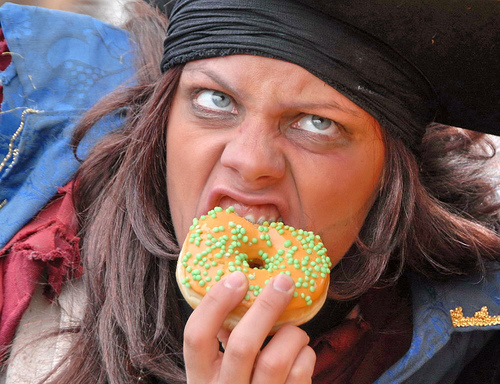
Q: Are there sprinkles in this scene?
A: Yes, there are sprinkles.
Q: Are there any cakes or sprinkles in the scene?
A: Yes, there are sprinkles.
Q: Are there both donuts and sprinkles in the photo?
A: Yes, there are both sprinkles and a donut.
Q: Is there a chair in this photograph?
A: No, there are no chairs.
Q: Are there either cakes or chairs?
A: No, there are no chairs or cakes.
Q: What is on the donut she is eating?
A: The sprinkles are on the donut.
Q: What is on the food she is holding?
A: The sprinkles are on the donut.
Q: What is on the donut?
A: The sprinkles are on the donut.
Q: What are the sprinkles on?
A: The sprinkles are on the donut.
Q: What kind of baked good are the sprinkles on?
A: The sprinkles are on the donut.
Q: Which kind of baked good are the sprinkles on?
A: The sprinkles are on the donut.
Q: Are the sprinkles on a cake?
A: No, the sprinkles are on the donut.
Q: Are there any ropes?
A: No, there are no ropes.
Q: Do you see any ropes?
A: No, there are no ropes.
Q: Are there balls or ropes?
A: No, there are no ropes or balls.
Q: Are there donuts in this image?
A: Yes, there is a donut.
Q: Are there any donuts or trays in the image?
A: Yes, there is a donut.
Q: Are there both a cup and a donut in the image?
A: No, there is a donut but no cups.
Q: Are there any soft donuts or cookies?
A: Yes, there is a soft donut.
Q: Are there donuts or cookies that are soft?
A: Yes, the donut is soft.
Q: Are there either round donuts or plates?
A: Yes, there is a round donut.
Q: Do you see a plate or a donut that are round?
A: Yes, the donut is round.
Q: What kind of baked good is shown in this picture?
A: The baked good is a donut.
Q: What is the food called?
A: The food is a donut.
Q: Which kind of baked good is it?
A: The food is a donut.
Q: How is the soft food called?
A: The food is a donut.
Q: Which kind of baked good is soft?
A: The baked good is a donut.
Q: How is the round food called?
A: The food is a donut.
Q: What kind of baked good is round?
A: The baked good is a donut.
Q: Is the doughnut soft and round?
A: Yes, the doughnut is soft and round.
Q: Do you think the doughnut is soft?
A: Yes, the doughnut is soft.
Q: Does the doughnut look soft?
A: Yes, the doughnut is soft.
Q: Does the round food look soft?
A: Yes, the doughnut is soft.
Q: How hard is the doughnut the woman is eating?
A: The doughnut is soft.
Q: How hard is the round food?
A: The doughnut is soft.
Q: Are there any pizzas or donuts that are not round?
A: No, there is a donut but it is round.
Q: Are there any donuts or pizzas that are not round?
A: No, there is a donut but it is round.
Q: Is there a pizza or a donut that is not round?
A: No, there is a donut but it is round.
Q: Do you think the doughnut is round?
A: Yes, the doughnut is round.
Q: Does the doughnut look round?
A: Yes, the doughnut is round.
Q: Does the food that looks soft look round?
A: Yes, the doughnut is round.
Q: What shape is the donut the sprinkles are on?
A: The donut is round.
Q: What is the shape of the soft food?
A: The donut is round.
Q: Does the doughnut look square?
A: No, the doughnut is round.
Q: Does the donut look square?
A: No, the donut is round.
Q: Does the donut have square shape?
A: No, the donut is round.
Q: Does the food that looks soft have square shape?
A: No, the donut is round.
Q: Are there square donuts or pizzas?
A: No, there is a donut but it is round.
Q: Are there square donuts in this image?
A: No, there is a donut but it is round.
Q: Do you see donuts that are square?
A: No, there is a donut but it is round.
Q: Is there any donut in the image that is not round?
A: No, there is a donut but it is round.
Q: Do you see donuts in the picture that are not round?
A: No, there is a donut but it is round.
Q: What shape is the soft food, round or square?
A: The donut is round.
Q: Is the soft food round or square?
A: The donut is round.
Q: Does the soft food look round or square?
A: The donut is round.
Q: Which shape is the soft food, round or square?
A: The donut is round.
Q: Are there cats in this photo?
A: No, there are no cats.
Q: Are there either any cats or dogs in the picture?
A: No, there are no cats or dogs.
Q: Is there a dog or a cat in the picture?
A: No, there are no cats or dogs.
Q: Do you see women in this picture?
A: Yes, there is a woman.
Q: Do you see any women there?
A: Yes, there is a woman.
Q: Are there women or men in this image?
A: Yes, there is a woman.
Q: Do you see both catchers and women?
A: No, there is a woman but no catchers.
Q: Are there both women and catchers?
A: No, there is a woman but no catchers.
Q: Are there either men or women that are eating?
A: Yes, the woman is eating.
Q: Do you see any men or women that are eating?
A: Yes, the woman is eating.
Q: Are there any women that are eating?
A: Yes, there is a woman that is eating.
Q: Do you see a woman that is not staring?
A: Yes, there is a woman that is eating .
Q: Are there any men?
A: No, there are no men.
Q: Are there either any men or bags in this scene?
A: No, there are no men or bags.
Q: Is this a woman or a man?
A: This is a woman.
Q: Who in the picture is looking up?
A: The woman is looking up.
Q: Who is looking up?
A: The woman is looking up.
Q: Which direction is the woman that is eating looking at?
A: The woman is looking up.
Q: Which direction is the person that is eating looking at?
A: The woman is looking up.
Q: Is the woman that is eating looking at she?
A: Yes, the woman is looking up.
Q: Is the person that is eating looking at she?
A: Yes, the woman is looking up.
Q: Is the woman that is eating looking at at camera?
A: No, the woman is looking up.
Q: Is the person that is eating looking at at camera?
A: No, the woman is looking up.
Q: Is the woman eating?
A: Yes, the woman is eating.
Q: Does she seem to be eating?
A: Yes, the woman is eating.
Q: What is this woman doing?
A: The woman is eating.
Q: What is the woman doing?
A: The woman is eating.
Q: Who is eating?
A: The woman is eating.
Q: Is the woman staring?
A: No, the woman is eating.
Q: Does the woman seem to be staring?
A: No, the woman is eating.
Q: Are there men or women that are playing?
A: No, there is a woman but she is eating.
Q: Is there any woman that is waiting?
A: No, there is a woman but she is eating.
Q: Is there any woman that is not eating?
A: No, there is a woman but she is eating.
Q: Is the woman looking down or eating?
A: The woman is eating.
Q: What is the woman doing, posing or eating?
A: The woman is eating.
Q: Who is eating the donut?
A: The woman is eating the donut.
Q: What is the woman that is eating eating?
A: The woman is eating a donut.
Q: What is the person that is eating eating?
A: The woman is eating a donut.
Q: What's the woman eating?
A: The woman is eating a donut.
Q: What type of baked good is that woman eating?
A: The woman is eating a doughnut.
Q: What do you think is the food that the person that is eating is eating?
A: The food is a donut.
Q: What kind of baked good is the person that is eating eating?
A: The woman is eating a doughnut.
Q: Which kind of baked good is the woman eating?
A: The woman is eating a doughnut.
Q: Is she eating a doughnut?
A: Yes, the woman is eating a doughnut.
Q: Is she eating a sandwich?
A: No, the woman is eating a doughnut.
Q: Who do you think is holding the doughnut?
A: The woman is holding the doughnut.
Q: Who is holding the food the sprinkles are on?
A: The woman is holding the doughnut.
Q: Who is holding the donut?
A: The woman is holding the doughnut.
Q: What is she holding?
A: The woman is holding the donut.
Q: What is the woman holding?
A: The woman is holding the donut.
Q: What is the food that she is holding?
A: The food is a donut.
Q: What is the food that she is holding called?
A: The food is a donut.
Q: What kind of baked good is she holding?
A: The woman is holding the donut.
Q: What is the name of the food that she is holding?
A: The food is a donut.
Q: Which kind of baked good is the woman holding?
A: The woman is holding the donut.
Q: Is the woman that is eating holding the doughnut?
A: Yes, the woman is holding the doughnut.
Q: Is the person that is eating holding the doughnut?
A: Yes, the woman is holding the doughnut.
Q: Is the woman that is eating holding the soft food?
A: Yes, the woman is holding the doughnut.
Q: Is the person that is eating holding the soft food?
A: Yes, the woman is holding the doughnut.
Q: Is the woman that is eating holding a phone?
A: No, the woman is holding the doughnut.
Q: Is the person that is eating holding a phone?
A: No, the woman is holding the doughnut.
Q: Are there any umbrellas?
A: No, there are no umbrellas.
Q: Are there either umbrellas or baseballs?
A: No, there are no umbrellas or baseballs.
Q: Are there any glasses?
A: No, there are no glasses.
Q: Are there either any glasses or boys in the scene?
A: No, there are no glasses or boys.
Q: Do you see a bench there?
A: No, there are no benches.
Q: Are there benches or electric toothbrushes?
A: No, there are no benches or electric toothbrushes.